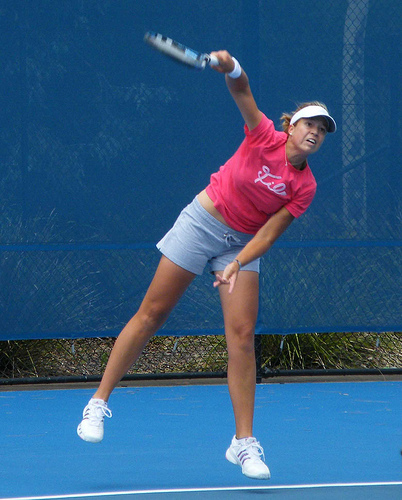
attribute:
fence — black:
[0, 1, 400, 338]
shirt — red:
[206, 115, 318, 230]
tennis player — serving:
[69, 47, 352, 484]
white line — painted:
[0, 478, 400, 497]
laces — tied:
[242, 438, 264, 459]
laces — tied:
[82, 399, 113, 416]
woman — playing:
[76, 47, 335, 478]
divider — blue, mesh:
[3, 2, 400, 340]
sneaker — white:
[226, 435, 270, 476]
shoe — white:
[227, 433, 274, 478]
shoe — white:
[76, 401, 107, 444]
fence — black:
[2, 331, 400, 387]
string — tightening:
[221, 231, 240, 252]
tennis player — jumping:
[75, 24, 336, 488]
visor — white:
[297, 102, 330, 128]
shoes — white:
[76, 396, 273, 478]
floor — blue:
[283, 379, 384, 448]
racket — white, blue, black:
[142, 31, 220, 67]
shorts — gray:
[132, 210, 284, 299]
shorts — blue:
[153, 198, 263, 277]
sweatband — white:
[226, 54, 243, 78]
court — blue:
[16, 46, 400, 473]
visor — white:
[275, 101, 343, 132]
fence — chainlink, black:
[0, 3, 400, 384]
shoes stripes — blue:
[222, 427, 278, 486]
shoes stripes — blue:
[67, 391, 123, 439]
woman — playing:
[115, 59, 375, 386]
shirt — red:
[220, 99, 324, 238]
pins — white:
[243, 442, 262, 453]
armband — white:
[223, 57, 244, 83]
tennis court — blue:
[7, 388, 398, 498]